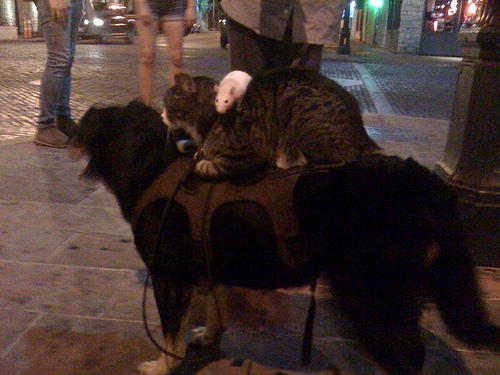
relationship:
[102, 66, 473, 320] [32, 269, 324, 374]
animals on sidewalk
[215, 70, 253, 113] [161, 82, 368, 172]
mouse on cat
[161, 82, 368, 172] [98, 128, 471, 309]
cat on dog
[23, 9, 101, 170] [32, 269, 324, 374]
person on sidewalk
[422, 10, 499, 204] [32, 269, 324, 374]
lampost on sidewalk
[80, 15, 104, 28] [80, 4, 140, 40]
headlight on car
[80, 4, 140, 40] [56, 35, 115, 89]
car on street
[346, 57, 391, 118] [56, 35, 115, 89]
line on street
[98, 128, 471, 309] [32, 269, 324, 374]
dog on sidewalk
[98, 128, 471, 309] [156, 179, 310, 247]
dog wearing vest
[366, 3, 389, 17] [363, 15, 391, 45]
light on wall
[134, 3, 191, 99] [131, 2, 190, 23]
woman wearing shorts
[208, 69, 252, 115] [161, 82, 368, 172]
mouse on cat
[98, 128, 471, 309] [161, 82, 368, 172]
dog near cat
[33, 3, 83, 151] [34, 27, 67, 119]
man wearing jean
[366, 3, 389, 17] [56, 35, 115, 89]
light on street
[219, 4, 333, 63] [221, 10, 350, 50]
person wearing trenchcoat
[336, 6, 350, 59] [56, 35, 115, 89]
poles on street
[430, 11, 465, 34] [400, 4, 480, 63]
window on store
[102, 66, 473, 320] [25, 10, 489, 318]
animals in picture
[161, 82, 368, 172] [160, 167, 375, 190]
cat on back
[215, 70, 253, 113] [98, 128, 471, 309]
mouse on dog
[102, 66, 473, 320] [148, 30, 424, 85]
animals on top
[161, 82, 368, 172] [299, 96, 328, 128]
cat has stripes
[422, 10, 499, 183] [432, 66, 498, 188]
lampost has base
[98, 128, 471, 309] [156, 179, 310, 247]
dog wearing harness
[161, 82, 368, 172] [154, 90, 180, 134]
cat has face